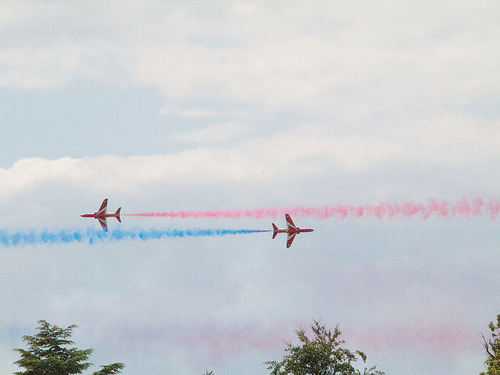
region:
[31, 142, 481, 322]
The planes flying by each other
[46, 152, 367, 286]
Both planes are pink and white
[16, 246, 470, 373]
Trees at the bottom of the image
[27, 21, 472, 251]
The sky is cloudy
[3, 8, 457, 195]
The sun is not out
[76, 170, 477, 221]
The air plan is spewing pink smoke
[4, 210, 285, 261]
This air plane is spewing blue smoke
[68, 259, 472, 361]
There is pink smoke here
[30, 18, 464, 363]
It is day time here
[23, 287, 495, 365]
These are tall trees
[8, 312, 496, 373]
Tall trees with green leaves in the foreground.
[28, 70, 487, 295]
Two planes flying through the sky.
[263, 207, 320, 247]
Red and white plane.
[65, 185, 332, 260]
Two planes flying in opposite directions.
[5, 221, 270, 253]
Blue smoke trailing one of the planes.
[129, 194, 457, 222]
Red smoke trailing one of the planes.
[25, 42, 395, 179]
Blue sky filled with puffy white clouds.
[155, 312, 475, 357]
Red cloud of red smoke lingering in the sky.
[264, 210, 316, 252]
Red plane with white stripes on it's wings.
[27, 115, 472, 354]
Two planes putting on a show for spectators.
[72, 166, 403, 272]
Two jets flying through the sky.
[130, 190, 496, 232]
The jet stream is red.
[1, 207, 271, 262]
The jet stream is blue.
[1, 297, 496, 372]
Green trees in the foreground.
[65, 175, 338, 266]
The jets are red with white stripes on the wings.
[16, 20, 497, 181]
The sky has clouds in it.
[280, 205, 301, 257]
The plane has two wings.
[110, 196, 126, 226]
The back of the airplane.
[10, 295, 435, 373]
Two green trees next to each other.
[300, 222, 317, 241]
The front of the plane.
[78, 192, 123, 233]
red and white plane in air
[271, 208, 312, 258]
red and white plane in air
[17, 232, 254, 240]
blue smoke emitted from red and white plane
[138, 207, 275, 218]
red smoke emitted from red and white plane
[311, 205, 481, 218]
red smoke emitted from red and white plane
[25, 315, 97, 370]
tree with green leaevs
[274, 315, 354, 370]
tree with green leaevs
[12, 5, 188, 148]
white clouds against blue sky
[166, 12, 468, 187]
white clouds against blue sky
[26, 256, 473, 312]
white clouds against blue sky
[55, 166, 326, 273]
a pair of red and white planes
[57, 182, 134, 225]
a plane with red smoke coming from it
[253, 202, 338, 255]
a plane with blue smoke coming from it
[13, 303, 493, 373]
the tops of some trees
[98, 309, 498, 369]
some red smoke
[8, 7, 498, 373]
a cloudy sky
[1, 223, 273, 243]
blue smoke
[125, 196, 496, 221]
red smoke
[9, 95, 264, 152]
a portion of the sky showing between clouds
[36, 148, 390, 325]
two planes doing a stunt